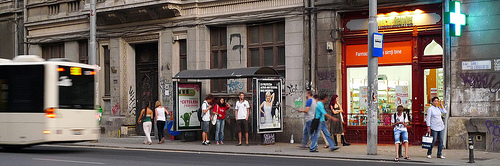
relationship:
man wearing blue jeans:
[308, 87, 338, 150] [309, 120, 337, 147]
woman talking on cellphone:
[417, 90, 454, 159] [433, 95, 445, 107]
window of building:
[247, 18, 285, 64] [25, 0, 311, 151]